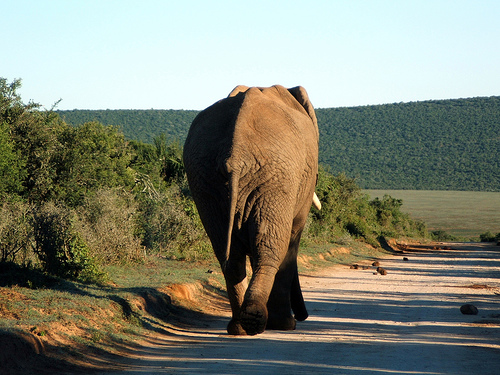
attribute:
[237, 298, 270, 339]
foot — back right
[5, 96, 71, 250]
shrubs — green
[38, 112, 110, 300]
shrubs — green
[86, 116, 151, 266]
shrubs — green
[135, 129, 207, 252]
shrubs — green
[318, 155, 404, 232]
shrubs — green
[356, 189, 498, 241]
field — large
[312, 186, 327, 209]
tusk — white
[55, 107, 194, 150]
forest — green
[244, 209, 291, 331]
leg — gray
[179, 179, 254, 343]
leg — back left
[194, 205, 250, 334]
hind leg — elephant's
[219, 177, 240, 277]
tail — elephant's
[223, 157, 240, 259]
tail — short, gray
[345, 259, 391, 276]
dung — brown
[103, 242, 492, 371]
road — dirt